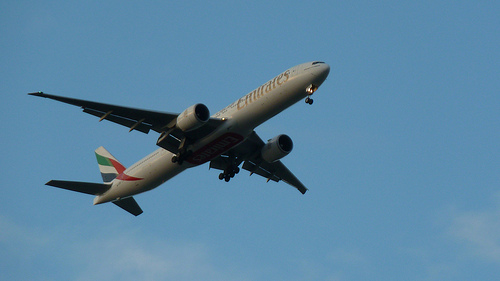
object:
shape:
[109, 158, 144, 181]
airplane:
[26, 62, 331, 217]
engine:
[262, 133, 294, 164]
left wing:
[221, 130, 309, 195]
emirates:
[237, 69, 291, 109]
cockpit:
[311, 60, 327, 74]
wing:
[26, 91, 221, 154]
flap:
[82, 108, 152, 134]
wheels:
[305, 98, 314, 105]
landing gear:
[305, 89, 314, 105]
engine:
[177, 103, 211, 133]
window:
[312, 62, 325, 65]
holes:
[279, 134, 292, 151]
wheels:
[172, 150, 194, 165]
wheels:
[219, 165, 240, 182]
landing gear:
[219, 164, 240, 182]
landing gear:
[171, 148, 192, 165]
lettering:
[236, 70, 289, 111]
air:
[0, 0, 498, 280]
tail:
[44, 169, 148, 216]